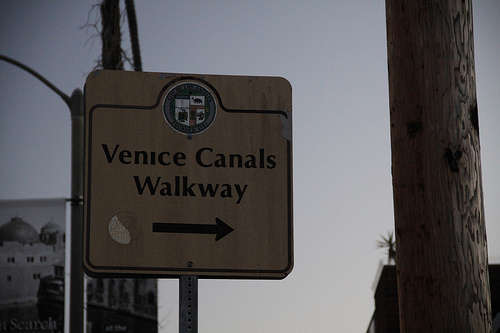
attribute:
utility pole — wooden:
[385, 4, 496, 331]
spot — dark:
[403, 113, 424, 139]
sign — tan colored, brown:
[79, 68, 296, 278]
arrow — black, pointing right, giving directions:
[149, 216, 235, 242]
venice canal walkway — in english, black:
[101, 138, 281, 209]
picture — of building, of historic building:
[1, 216, 68, 317]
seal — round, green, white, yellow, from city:
[163, 81, 217, 132]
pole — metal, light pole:
[175, 273, 202, 331]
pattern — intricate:
[451, 12, 471, 95]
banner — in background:
[1, 196, 66, 332]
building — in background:
[368, 253, 500, 331]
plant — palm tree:
[379, 229, 401, 258]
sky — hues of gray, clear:
[3, 4, 497, 332]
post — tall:
[68, 81, 88, 332]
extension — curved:
[1, 51, 71, 110]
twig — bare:
[117, 4, 135, 75]